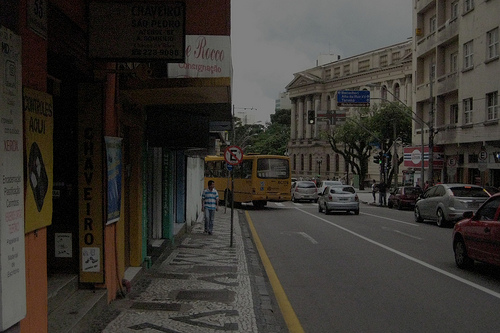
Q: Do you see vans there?
A: No, there are no vans.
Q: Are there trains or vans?
A: No, there are no vans or trains.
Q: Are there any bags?
A: No, there are no bags.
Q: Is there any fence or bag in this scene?
A: No, there are no bags or fences.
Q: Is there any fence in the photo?
A: No, there are no fences.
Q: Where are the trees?
A: The trees are on the sidewalk.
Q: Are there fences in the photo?
A: No, there are no fences.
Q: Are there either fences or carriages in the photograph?
A: No, there are no fences or carriages.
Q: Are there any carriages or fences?
A: No, there are no fences or carriages.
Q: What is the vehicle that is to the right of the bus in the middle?
A: The vehicle is a car.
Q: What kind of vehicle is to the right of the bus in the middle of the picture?
A: The vehicle is a car.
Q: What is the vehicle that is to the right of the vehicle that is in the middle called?
A: The vehicle is a car.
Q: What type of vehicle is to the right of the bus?
A: The vehicle is a car.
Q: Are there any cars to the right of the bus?
A: Yes, there is a car to the right of the bus.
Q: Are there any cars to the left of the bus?
A: No, the car is to the right of the bus.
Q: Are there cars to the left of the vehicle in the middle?
A: No, the car is to the right of the bus.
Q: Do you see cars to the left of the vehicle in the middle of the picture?
A: No, the car is to the right of the bus.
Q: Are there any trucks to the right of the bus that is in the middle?
A: No, there is a car to the right of the bus.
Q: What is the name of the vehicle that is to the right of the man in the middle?
A: The vehicle is a car.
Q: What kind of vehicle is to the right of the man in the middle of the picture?
A: The vehicle is a car.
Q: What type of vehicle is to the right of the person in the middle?
A: The vehicle is a car.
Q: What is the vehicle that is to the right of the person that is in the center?
A: The vehicle is a car.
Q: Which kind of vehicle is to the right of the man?
A: The vehicle is a car.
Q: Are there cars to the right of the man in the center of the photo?
A: Yes, there is a car to the right of the man.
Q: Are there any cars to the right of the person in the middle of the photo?
A: Yes, there is a car to the right of the man.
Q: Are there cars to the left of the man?
A: No, the car is to the right of the man.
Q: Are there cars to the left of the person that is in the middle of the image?
A: No, the car is to the right of the man.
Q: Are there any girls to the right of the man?
A: No, there is a car to the right of the man.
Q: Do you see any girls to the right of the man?
A: No, there is a car to the right of the man.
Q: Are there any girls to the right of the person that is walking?
A: No, there is a car to the right of the man.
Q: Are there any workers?
A: No, there are no workers.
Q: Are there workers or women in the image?
A: No, there are no workers or women.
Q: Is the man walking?
A: Yes, the man is walking.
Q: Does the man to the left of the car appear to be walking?
A: Yes, the man is walking.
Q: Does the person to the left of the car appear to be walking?
A: Yes, the man is walking.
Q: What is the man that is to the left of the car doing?
A: The man is walking.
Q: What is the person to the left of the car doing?
A: The man is walking.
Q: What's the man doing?
A: The man is walking.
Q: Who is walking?
A: The man is walking.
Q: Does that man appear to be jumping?
A: No, the man is walking.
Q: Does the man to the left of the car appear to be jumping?
A: No, the man is walking.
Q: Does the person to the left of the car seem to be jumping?
A: No, the man is walking.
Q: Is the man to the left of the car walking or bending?
A: The man is walking.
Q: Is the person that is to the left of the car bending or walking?
A: The man is walking.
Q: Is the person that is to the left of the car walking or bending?
A: The man is walking.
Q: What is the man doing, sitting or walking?
A: The man is walking.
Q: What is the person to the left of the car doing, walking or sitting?
A: The man is walking.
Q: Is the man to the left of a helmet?
A: No, the man is to the left of the car.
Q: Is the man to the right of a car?
A: No, the man is to the left of a car.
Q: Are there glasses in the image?
A: No, there are no glasses.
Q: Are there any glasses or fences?
A: No, there are no glasses or fences.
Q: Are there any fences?
A: No, there are no fences.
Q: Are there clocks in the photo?
A: No, there are no clocks.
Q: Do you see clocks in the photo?
A: No, there are no clocks.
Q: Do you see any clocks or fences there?
A: No, there are no clocks or fences.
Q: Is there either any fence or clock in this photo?
A: No, there are no clocks or fences.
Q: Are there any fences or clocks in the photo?
A: No, there are no clocks or fences.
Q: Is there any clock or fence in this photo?
A: No, there are no clocks or fences.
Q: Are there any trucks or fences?
A: No, there are no fences or trucks.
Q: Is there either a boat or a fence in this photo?
A: No, there are no fences or boats.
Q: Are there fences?
A: No, there are no fences.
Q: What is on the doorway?
A: The sign is on the doorway.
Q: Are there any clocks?
A: No, there are no clocks.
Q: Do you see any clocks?
A: No, there are no clocks.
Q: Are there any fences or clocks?
A: No, there are no clocks or fences.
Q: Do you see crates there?
A: No, there are no crates.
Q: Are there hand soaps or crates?
A: No, there are no crates or hand soaps.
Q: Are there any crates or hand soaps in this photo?
A: No, there are no crates or hand soaps.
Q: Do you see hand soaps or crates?
A: No, there are no crates or hand soaps.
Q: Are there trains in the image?
A: No, there are no trains.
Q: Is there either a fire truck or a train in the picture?
A: No, there are no trains or fire trucks.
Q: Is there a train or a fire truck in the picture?
A: No, there are no trains or fire trucks.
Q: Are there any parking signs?
A: Yes, there is a parking sign.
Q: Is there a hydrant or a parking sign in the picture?
A: Yes, there is a parking sign.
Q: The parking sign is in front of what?
A: The parking sign is in front of the building.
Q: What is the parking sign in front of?
A: The parking sign is in front of the building.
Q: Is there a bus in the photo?
A: Yes, there is a bus.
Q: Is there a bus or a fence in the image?
A: Yes, there is a bus.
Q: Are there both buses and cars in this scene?
A: Yes, there are both a bus and a car.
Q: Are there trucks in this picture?
A: No, there are no trucks.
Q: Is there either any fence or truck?
A: No, there are no trucks or fences.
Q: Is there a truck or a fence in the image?
A: No, there are no trucks or fences.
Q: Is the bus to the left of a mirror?
A: No, the bus is to the left of a car.